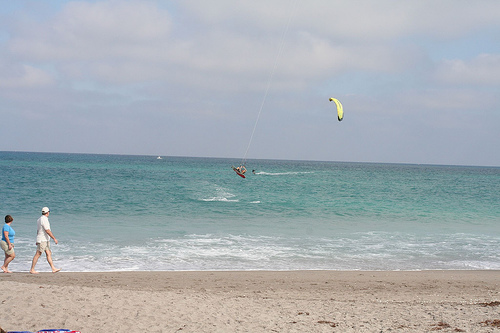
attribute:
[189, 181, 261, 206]
wave — waves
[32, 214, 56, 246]
shirt — white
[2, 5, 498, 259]
distance — far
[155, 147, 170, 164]
boat — white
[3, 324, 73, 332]
towel — blue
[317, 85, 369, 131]
kite — yellow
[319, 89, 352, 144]
kite — yellow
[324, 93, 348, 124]
kite — yellow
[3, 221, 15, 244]
shirt — blue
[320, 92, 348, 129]
sail — yellow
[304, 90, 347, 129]
kite — yellow and black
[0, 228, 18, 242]
shirt — blue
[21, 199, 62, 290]
man — walking